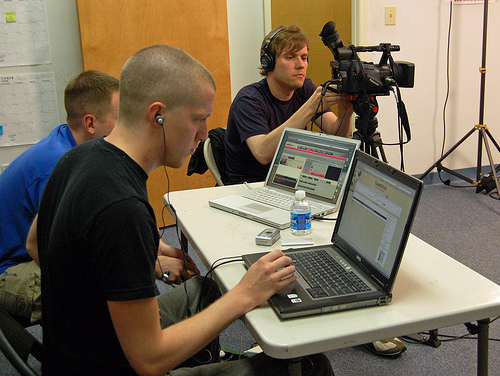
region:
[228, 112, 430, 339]
Two laptops sitting on table.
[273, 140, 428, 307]
An open black laptop.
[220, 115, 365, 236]
An open white laptop.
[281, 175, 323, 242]
A plastic bottle of water.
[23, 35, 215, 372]
Young man in black tee shirt.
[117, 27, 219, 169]
Young man with close haircut.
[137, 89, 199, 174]
Earphones hooked to laptop.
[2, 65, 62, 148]
A calendar on the wall.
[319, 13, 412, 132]
Black recording equipment.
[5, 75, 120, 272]
Young man in blue tee shirt.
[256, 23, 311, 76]
Headphones on a man's head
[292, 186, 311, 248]
Water bottle on the table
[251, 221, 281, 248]
Cell phone on the table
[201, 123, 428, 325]
Two lap top computers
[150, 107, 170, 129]
Ear bud head phone in an ear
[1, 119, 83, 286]
Blue shirt on a man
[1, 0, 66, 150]
Two calendars on the wall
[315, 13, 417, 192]
A black video camera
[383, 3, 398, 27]
A rectangular light switch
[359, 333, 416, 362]
The toe of a sneaker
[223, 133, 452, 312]
Two laptops are seen.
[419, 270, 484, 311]
Table is white in color.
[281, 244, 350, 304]
Laptop is black in color.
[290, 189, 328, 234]
One water bottle is seen.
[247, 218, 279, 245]
Grey color mobile is in the table.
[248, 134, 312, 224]
Laptop is white in color.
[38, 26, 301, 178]
Three boys are seen.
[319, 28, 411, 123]
Camera is black in color.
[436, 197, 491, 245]
Floor is grey in color.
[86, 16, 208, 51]
Door is brown in color.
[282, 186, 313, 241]
small bottle of water on the table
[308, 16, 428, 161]
the black camera on a tripod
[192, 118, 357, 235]
the white laptop on the left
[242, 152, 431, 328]
the black laptop on the right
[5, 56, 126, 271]
the young man in the blue t-shirt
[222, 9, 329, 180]
the man wearing large earphones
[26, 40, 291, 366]
the young man wearing small headphones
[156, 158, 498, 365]
small white folding table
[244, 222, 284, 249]
a silver flip phone on the desk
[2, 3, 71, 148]
two calendars hanging on the wall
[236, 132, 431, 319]
black laptop on desk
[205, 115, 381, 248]
silver lap top on desk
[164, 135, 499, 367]
white rectangular table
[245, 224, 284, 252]
silver cellphone on the table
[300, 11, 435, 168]
camera on a stand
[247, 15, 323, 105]
man wearing headphones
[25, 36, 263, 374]
man has earphones in his ears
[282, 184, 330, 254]
small water bottle on the table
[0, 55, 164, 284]
man wearing blue shirt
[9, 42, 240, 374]
man wearing black shirt